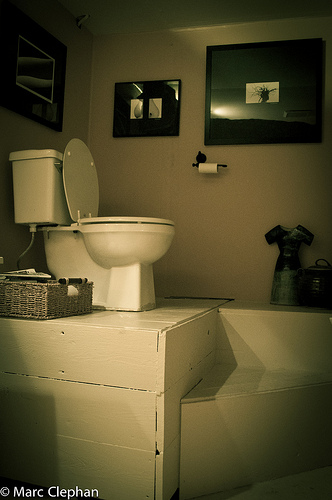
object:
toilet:
[62, 138, 175, 311]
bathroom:
[1, 9, 325, 497]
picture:
[204, 38, 326, 147]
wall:
[4, 0, 326, 301]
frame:
[113, 79, 182, 138]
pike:
[0, 10, 68, 134]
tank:
[9, 149, 73, 227]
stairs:
[178, 308, 332, 499]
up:
[180, 293, 332, 406]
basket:
[0, 277, 95, 321]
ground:
[0, 277, 167, 399]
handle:
[218, 163, 228, 168]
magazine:
[0, 268, 51, 279]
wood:
[176, 383, 332, 496]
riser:
[164, 308, 331, 394]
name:
[0, 483, 102, 500]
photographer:
[1, 484, 98, 498]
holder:
[192, 151, 227, 169]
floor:
[50, 301, 332, 335]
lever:
[54, 162, 63, 174]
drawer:
[0, 372, 162, 453]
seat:
[63, 138, 176, 226]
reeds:
[0, 277, 94, 321]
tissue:
[199, 163, 219, 174]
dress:
[264, 224, 314, 306]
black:
[115, 120, 124, 133]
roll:
[198, 162, 218, 173]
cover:
[9, 149, 64, 163]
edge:
[163, 295, 235, 303]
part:
[1, 317, 161, 396]